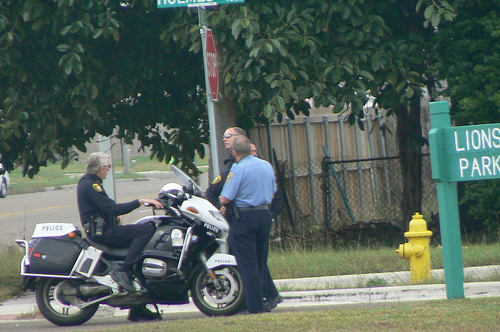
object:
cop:
[77, 150, 164, 321]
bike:
[14, 164, 244, 326]